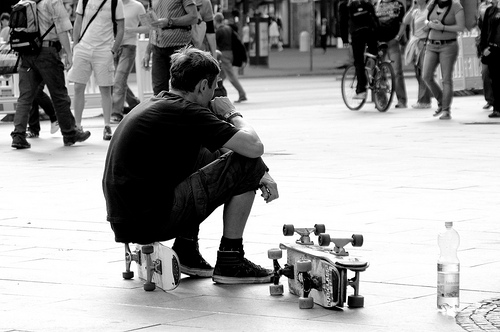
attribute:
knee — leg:
[229, 145, 266, 181]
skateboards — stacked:
[266, 222, 370, 311]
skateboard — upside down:
[267, 209, 376, 279]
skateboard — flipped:
[119, 237, 185, 293]